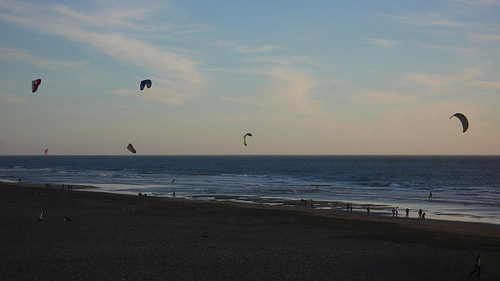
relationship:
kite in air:
[450, 110, 479, 137] [322, 37, 408, 164]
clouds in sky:
[0, 0, 499, 154] [296, 5, 423, 90]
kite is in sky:
[30, 77, 42, 93] [140, 5, 485, 74]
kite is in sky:
[137, 75, 156, 92] [140, 5, 485, 74]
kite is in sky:
[239, 129, 253, 146] [140, 5, 485, 74]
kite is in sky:
[451, 112, 469, 136] [140, 5, 485, 74]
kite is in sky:
[132, 72, 159, 93] [89, 45, 143, 92]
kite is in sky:
[108, 67, 195, 118] [124, 10, 388, 108]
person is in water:
[366, 201, 371, 211] [3, 152, 498, 217]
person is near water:
[366, 201, 371, 211] [3, 152, 498, 217]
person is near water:
[348, 204, 353, 210] [3, 152, 498, 217]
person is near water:
[344, 202, 350, 209] [3, 152, 498, 217]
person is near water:
[404, 207, 409, 217] [3, 152, 498, 217]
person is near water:
[389, 202, 395, 217] [3, 152, 498, 217]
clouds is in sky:
[181, 53, 361, 107] [116, 19, 493, 146]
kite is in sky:
[242, 131, 252, 146] [2, 6, 495, 150]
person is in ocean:
[424, 187, 436, 202] [1, 151, 499, 227]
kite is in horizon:
[40, 144, 55, 161] [16, 138, 476, 149]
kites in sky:
[24, 67, 479, 165] [2, 6, 495, 150]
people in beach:
[282, 186, 442, 226] [1, 186, 490, 273]